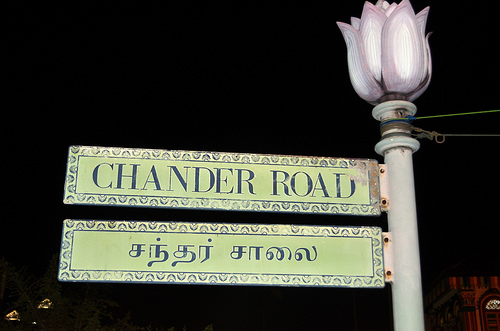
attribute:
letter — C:
[91, 160, 113, 190]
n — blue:
[164, 156, 191, 202]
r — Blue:
[269, 168, 292, 198]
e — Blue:
[213, 165, 235, 196]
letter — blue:
[114, 150, 145, 201]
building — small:
[424, 261, 498, 326]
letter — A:
[141, 161, 164, 194]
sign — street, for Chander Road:
[52, 136, 395, 221]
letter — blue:
[192, 165, 215, 192]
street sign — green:
[63, 144, 381, 216]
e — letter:
[210, 166, 237, 193]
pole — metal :
[357, 105, 443, 329]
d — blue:
[189, 163, 217, 193]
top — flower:
[334, 4, 434, 104]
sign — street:
[54, 218, 385, 288]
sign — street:
[76, 114, 413, 316]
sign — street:
[108, 131, 407, 233]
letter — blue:
[89, 160, 116, 190]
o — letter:
[291, 171, 312, 196]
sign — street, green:
[46, 140, 334, 213]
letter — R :
[266, 168, 287, 200]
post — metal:
[374, 97, 429, 329]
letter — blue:
[215, 162, 237, 193]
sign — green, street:
[60, 144, 384, 219]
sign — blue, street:
[15, 154, 302, 251]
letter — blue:
[232, 165, 259, 198]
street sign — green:
[53, 128, 414, 299]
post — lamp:
[335, 2, 435, 329]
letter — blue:
[269, 169, 292, 199]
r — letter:
[235, 160, 256, 198]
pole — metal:
[371, 109, 438, 329]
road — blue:
[269, 165, 362, 204]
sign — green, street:
[81, 152, 371, 287]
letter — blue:
[112, 155, 143, 195]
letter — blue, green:
[190, 156, 221, 201]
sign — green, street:
[53, 131, 397, 291]